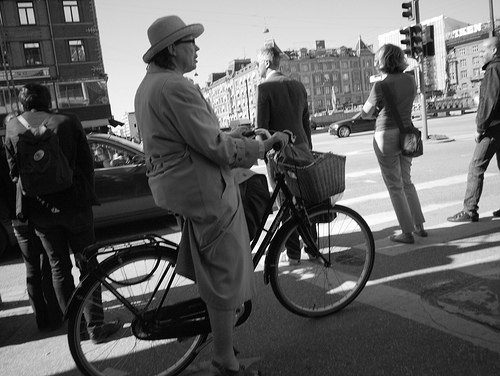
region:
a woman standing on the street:
[354, 43, 431, 253]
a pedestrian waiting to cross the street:
[351, 39, 430, 246]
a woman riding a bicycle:
[59, 11, 380, 373]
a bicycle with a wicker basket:
[53, 123, 378, 373]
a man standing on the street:
[454, 32, 499, 221]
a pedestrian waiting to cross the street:
[449, 29, 499, 226]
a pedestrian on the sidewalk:
[2, 80, 117, 341]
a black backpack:
[8, 112, 75, 204]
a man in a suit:
[244, 45, 324, 262]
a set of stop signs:
[396, 0, 439, 147]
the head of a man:
[253, 44, 284, 81]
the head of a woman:
[372, 40, 411, 82]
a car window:
[79, 131, 146, 168]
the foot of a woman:
[386, 227, 421, 249]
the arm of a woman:
[354, 80, 379, 123]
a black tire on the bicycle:
[260, 196, 379, 319]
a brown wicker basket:
[271, 145, 347, 207]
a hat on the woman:
[134, 12, 203, 64]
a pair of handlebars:
[240, 122, 297, 154]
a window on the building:
[58, 0, 86, 26]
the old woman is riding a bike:
[127, 20, 292, 336]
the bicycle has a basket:
[262, 137, 352, 199]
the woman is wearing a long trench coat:
[132, 63, 289, 310]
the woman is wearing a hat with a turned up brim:
[137, 11, 211, 61]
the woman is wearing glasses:
[170, 35, 202, 52]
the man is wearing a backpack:
[3, 83, 90, 215]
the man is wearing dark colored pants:
[20, 214, 112, 354]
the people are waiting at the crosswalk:
[239, 59, 467, 241]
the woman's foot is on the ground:
[205, 341, 266, 374]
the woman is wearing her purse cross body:
[360, 75, 441, 183]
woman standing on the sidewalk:
[340, 41, 438, 242]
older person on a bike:
[68, 18, 383, 375]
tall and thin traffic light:
[398, 1, 436, 138]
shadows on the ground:
[9, 221, 493, 374]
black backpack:
[6, 118, 88, 226]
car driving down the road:
[329, 104, 393, 140]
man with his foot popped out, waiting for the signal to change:
[449, 36, 499, 226]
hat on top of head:
[129, 11, 212, 75]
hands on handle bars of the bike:
[226, 112, 307, 172]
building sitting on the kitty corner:
[194, 30, 394, 139]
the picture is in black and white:
[3, 0, 495, 369]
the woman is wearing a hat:
[131, 10, 225, 69]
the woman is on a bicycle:
[46, 0, 377, 375]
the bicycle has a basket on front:
[262, 127, 384, 227]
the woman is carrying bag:
[378, 81, 433, 160]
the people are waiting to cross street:
[352, 31, 497, 238]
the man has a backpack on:
[1, 76, 120, 259]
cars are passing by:
[318, 83, 487, 151]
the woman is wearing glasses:
[160, 27, 209, 52]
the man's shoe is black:
[444, 202, 494, 235]